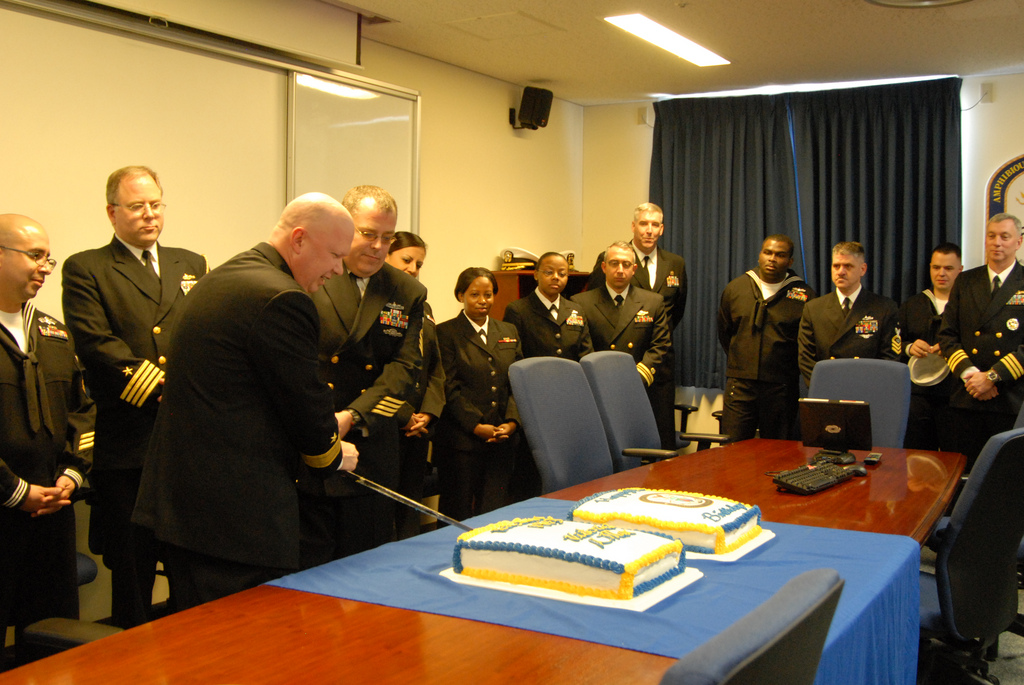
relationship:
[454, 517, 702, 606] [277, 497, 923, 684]
cake on right side of cloth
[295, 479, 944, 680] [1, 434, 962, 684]
cloth on middle of table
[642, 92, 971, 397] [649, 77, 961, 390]
curtains in front of curtains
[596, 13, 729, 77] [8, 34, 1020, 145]
light in ceiling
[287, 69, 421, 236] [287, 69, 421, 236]
board in board